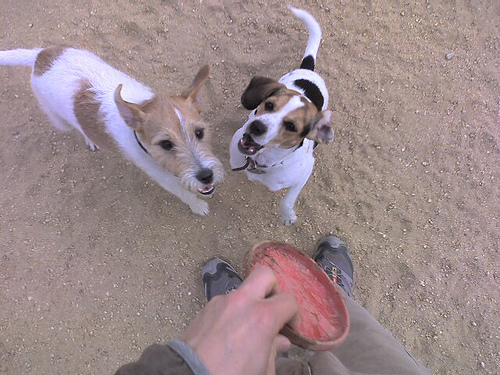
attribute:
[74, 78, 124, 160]
spot — brown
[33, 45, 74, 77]
spot — brown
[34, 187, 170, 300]
pebbles — small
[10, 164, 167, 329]
pebbles — brown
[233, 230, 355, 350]
disc — red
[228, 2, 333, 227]
dog — white, black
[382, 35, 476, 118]
pebbles — small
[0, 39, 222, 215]
dog — brown, white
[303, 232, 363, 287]
shoes — brown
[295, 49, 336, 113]
spots — black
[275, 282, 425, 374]
pants — brown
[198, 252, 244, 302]
shoe — brown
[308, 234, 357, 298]
shoe — brown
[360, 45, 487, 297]
dirt — brown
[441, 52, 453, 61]
pebbles — small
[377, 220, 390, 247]
pebbles — small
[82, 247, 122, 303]
pebbles — small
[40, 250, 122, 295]
pebbles — small